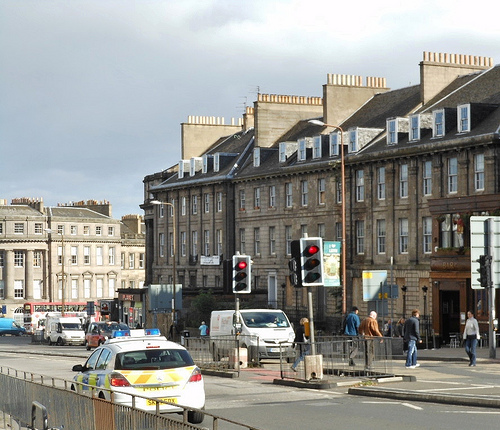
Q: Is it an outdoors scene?
A: Yes, it is outdoors.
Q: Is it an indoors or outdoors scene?
A: It is outdoors.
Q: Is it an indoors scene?
A: No, it is outdoors.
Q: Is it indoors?
A: No, it is outdoors.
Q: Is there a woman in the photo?
A: Yes, there is a woman.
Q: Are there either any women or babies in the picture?
A: Yes, there is a woman.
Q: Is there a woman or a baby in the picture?
A: Yes, there is a woman.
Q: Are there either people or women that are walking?
A: Yes, the woman is walking.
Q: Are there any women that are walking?
A: Yes, there is a woman that is walking.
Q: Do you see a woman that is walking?
A: Yes, there is a woman that is walking.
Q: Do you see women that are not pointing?
A: Yes, there is a woman that is walking .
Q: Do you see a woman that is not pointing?
A: Yes, there is a woman that is walking .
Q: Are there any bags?
A: No, there are no bags.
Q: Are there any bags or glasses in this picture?
A: No, there are no bags or glasses.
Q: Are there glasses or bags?
A: No, there are no bags or glasses.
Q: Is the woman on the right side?
A: Yes, the woman is on the right of the image.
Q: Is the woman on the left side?
A: No, the woman is on the right of the image.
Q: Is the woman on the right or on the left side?
A: The woman is on the right of the image.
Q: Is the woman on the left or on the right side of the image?
A: The woman is on the right of the image.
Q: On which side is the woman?
A: The woman is on the right of the image.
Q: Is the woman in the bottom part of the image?
A: Yes, the woman is in the bottom of the image.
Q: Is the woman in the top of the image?
A: No, the woman is in the bottom of the image.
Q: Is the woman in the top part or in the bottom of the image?
A: The woman is in the bottom of the image.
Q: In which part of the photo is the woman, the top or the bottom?
A: The woman is in the bottom of the image.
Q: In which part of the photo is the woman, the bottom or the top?
A: The woman is in the bottom of the image.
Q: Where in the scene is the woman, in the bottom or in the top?
A: The woman is in the bottom of the image.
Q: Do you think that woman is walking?
A: Yes, the woman is walking.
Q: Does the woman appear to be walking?
A: Yes, the woman is walking.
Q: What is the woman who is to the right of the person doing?
A: The woman is walking.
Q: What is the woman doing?
A: The woman is walking.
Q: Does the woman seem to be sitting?
A: No, the woman is walking.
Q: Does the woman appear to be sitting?
A: No, the woman is walking.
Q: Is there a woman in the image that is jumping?
A: No, there is a woman but she is walking.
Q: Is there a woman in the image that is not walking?
A: No, there is a woman but she is walking.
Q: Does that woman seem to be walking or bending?
A: The woman is walking.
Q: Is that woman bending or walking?
A: The woman is walking.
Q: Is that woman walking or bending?
A: The woman is walking.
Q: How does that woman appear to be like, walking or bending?
A: The woman is walking.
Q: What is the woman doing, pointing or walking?
A: The woman is walking.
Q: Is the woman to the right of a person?
A: Yes, the woman is to the right of a person.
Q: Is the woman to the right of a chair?
A: No, the woman is to the right of a person.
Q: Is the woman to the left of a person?
A: No, the woman is to the right of a person.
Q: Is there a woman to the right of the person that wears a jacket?
A: Yes, there is a woman to the right of the person.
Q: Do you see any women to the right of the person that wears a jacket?
A: Yes, there is a woman to the right of the person.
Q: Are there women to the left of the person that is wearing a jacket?
A: No, the woman is to the right of the person.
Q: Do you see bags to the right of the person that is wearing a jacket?
A: No, there is a woman to the right of the person.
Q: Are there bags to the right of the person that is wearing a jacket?
A: No, there is a woman to the right of the person.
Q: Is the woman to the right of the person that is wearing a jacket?
A: Yes, the woman is to the right of the person.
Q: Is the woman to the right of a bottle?
A: No, the woman is to the right of the person.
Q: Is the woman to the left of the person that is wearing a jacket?
A: No, the woman is to the right of the person.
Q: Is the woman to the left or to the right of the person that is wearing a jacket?
A: The woman is to the right of the person.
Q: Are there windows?
A: Yes, there is a window.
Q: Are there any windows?
A: Yes, there is a window.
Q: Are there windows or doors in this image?
A: Yes, there is a window.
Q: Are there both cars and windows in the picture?
A: Yes, there are both a window and a car.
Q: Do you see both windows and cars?
A: Yes, there are both a window and a car.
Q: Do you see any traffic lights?
A: Yes, there is a traffic light.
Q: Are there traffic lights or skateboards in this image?
A: Yes, there is a traffic light.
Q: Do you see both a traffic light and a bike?
A: No, there is a traffic light but no bikes.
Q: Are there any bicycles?
A: No, there are no bicycles.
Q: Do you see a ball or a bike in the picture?
A: No, there are no bikes or balls.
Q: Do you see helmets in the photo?
A: No, there are no helmets.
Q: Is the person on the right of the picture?
A: Yes, the person is on the right of the image.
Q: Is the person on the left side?
A: No, the person is on the right of the image.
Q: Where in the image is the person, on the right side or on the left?
A: The person is on the right of the image.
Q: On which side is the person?
A: The person is on the right of the image.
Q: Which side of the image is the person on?
A: The person is on the right of the image.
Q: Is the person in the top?
A: No, the person is in the bottom of the image.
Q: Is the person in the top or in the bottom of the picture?
A: The person is in the bottom of the image.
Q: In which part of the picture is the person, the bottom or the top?
A: The person is in the bottom of the image.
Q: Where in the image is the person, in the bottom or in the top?
A: The person is in the bottom of the image.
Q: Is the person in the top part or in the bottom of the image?
A: The person is in the bottom of the image.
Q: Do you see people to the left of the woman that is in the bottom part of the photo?
A: Yes, there is a person to the left of the woman.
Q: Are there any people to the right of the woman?
A: No, the person is to the left of the woman.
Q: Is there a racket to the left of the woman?
A: No, there is a person to the left of the woman.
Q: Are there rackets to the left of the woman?
A: No, there is a person to the left of the woman.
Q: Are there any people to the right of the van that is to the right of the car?
A: Yes, there is a person to the right of the van.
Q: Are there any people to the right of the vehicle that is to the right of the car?
A: Yes, there is a person to the right of the van.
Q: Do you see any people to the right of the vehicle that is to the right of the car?
A: Yes, there is a person to the right of the van.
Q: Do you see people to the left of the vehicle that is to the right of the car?
A: No, the person is to the right of the van.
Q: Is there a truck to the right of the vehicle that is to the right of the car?
A: No, there is a person to the right of the van.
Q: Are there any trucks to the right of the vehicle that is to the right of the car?
A: No, there is a person to the right of the van.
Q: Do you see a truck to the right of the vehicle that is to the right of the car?
A: No, there is a person to the right of the van.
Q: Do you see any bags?
A: No, there are no bags.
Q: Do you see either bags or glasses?
A: No, there are no bags or glasses.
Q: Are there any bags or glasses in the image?
A: No, there are no bags or glasses.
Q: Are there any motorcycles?
A: No, there are no motorcycles.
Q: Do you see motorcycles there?
A: No, there are no motorcycles.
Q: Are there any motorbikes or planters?
A: No, there are no motorbikes or planters.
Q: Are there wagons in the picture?
A: No, there are no wagons.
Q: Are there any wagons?
A: No, there are no wagons.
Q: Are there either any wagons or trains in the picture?
A: No, there are no wagons or trains.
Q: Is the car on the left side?
A: Yes, the car is on the left of the image.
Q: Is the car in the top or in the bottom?
A: The car is in the bottom of the image.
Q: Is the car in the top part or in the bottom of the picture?
A: The car is in the bottom of the image.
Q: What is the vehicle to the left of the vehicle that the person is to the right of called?
A: The vehicle is a car.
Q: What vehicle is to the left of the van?
A: The vehicle is a car.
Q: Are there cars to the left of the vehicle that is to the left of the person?
A: Yes, there is a car to the left of the van.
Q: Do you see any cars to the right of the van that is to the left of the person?
A: No, the car is to the left of the van.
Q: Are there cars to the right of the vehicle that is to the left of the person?
A: No, the car is to the left of the van.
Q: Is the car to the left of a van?
A: Yes, the car is to the left of a van.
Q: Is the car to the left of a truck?
A: No, the car is to the left of a van.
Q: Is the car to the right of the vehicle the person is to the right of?
A: No, the car is to the left of the van.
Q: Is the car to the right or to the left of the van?
A: The car is to the left of the van.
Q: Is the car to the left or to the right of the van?
A: The car is to the left of the van.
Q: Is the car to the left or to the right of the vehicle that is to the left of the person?
A: The car is to the left of the van.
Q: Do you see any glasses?
A: No, there are no glasses.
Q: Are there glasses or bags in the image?
A: No, there are no glasses or bags.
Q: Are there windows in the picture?
A: Yes, there is a window.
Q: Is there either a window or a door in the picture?
A: Yes, there is a window.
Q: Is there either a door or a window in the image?
A: Yes, there is a window.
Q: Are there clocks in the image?
A: No, there are no clocks.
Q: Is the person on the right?
A: Yes, the person is on the right of the image.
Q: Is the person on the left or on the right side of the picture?
A: The person is on the right of the image.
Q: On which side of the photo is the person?
A: The person is on the right of the image.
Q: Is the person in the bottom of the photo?
A: Yes, the person is in the bottom of the image.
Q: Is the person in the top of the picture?
A: No, the person is in the bottom of the image.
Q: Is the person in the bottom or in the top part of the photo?
A: The person is in the bottom of the image.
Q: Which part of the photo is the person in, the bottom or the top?
A: The person is in the bottom of the image.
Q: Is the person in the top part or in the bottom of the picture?
A: The person is in the bottom of the image.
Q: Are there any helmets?
A: No, there are no helmets.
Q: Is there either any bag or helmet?
A: No, there are no helmets or bags.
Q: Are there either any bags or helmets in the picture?
A: No, there are no helmets or bags.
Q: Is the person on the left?
A: No, the person is on the right of the image.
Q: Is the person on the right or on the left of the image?
A: The person is on the right of the image.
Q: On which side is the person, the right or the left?
A: The person is on the right of the image.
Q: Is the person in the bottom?
A: Yes, the person is in the bottom of the image.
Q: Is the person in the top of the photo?
A: No, the person is in the bottom of the image.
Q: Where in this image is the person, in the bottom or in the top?
A: The person is in the bottom of the image.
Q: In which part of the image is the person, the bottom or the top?
A: The person is in the bottom of the image.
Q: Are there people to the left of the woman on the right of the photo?
A: Yes, there is a person to the left of the woman.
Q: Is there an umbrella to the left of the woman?
A: No, there is a person to the left of the woman.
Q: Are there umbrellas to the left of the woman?
A: No, there is a person to the left of the woman.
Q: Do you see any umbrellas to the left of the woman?
A: No, there is a person to the left of the woman.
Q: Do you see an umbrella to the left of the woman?
A: No, there is a person to the left of the woman.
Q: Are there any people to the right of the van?
A: Yes, there is a person to the right of the van.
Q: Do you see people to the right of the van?
A: Yes, there is a person to the right of the van.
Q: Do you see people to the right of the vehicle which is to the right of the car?
A: Yes, there is a person to the right of the van.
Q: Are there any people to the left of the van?
A: No, the person is to the right of the van.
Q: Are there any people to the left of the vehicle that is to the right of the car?
A: No, the person is to the right of the van.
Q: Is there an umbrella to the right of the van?
A: No, there is a person to the right of the van.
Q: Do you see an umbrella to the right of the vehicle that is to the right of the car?
A: No, there is a person to the right of the van.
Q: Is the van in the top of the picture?
A: No, the van is in the bottom of the image.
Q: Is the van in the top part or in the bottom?
A: The van is in the bottom of the image.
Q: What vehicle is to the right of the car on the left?
A: The vehicle is a van.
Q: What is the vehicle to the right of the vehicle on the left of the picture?
A: The vehicle is a van.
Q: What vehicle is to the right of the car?
A: The vehicle is a van.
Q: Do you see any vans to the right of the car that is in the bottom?
A: Yes, there is a van to the right of the car.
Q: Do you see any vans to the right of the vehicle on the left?
A: Yes, there is a van to the right of the car.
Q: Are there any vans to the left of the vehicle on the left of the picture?
A: No, the van is to the right of the car.